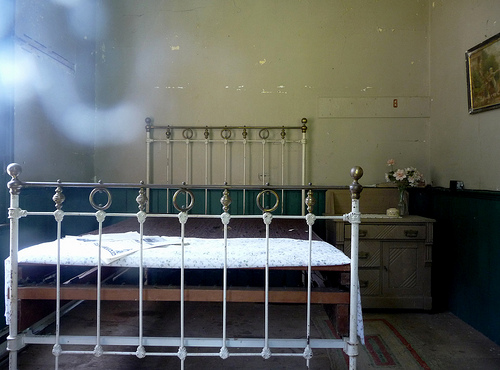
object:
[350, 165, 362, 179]
knob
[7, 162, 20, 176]
knob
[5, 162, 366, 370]
foot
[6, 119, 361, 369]
bed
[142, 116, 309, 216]
headboard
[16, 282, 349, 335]
stand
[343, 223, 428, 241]
drawer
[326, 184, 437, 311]
stand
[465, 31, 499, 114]
painting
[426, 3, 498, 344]
wall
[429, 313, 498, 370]
part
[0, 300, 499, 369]
carpet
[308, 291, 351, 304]
part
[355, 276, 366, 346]
edge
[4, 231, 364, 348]
sheet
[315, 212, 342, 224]
part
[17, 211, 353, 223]
metal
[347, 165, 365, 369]
bedpost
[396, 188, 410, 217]
bottle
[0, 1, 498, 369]
bedroom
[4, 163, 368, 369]
footboard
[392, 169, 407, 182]
flowers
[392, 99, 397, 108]
8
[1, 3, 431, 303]
wall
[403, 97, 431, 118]
tile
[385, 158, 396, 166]
flower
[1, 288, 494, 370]
floor